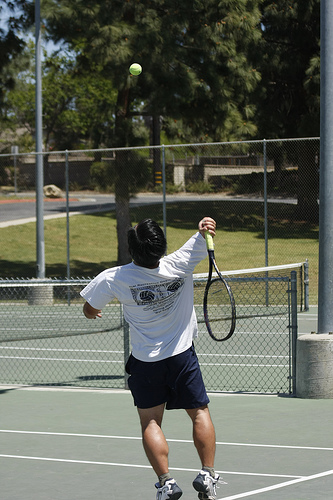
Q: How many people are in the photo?
A: One.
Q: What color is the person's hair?
A: Black.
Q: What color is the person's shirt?
A: White.